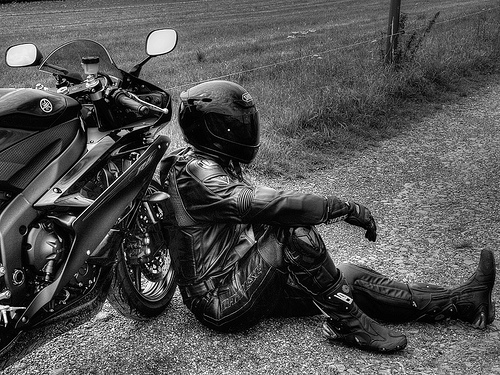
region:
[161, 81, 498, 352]
a motorcyclist resting on street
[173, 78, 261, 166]
a black motorcycle helmet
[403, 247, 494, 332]
a black motorcycle boot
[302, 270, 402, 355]
a black motorcycle boot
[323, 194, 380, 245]
a black motorcycle glove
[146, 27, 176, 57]
a motorcycle rear view mirror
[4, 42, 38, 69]
a motorcycle rear view mirror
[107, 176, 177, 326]
a motorcycle front tire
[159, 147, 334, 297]
a motorcycle leather jacket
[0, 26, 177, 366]
a parked black motorcycle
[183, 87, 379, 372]
this is a man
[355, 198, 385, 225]
this is a glove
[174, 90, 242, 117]
this is a helmet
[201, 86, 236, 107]
the helmet is black in color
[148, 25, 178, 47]
this is a mirror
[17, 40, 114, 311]
this is a motorbike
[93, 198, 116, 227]
the motorbike is black in color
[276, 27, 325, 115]
this is a grass area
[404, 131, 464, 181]
this is a road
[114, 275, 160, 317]
this is the wheel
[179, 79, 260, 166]
the man is wearing a helmet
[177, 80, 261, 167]
the helmet is black in tone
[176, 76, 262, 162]
the helmet is shiny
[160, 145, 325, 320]
the man is wearng a jacket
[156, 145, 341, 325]
the jacket is made of color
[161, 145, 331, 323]
the jacket is made of metal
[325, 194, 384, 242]
the man is wearing gloves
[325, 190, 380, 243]
the gloves are black in tone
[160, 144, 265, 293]
the jacket is black in tone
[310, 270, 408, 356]
the man is wearing boots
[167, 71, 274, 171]
motorcycle helmet with black shield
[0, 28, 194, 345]
parked motorcycle on cement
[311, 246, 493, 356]
two motorcycle long boots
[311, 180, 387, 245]
right hand motorcycle glove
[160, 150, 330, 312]
thick padded motorcycle jacket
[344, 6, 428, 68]
wired wooden pole fence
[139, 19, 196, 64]
motorcycle rear view mirror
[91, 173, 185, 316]
motorcycle wheel with chrome rim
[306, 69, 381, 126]
thick grass bushes by fence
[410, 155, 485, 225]
gravel road with dirt and debris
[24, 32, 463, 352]
This photo is monochromatic style.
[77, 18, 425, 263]
The photo is in black and white.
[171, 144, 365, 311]
The man is wearing leather.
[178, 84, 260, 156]
The man has a helmet on.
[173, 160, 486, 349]
The man is wearing protective gear.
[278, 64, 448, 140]
The ground here is grass.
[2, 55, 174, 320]
This is a motorcycle.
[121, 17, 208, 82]
This is a side mirror.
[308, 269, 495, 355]
These are boots.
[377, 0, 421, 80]
This is a fence post.